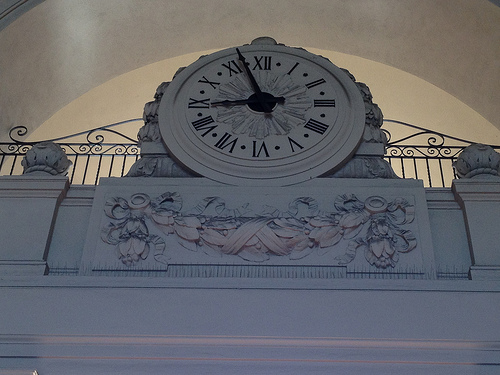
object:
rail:
[380, 116, 500, 187]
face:
[183, 50, 338, 162]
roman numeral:
[252, 54, 272, 70]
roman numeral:
[305, 78, 327, 90]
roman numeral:
[303, 117, 330, 135]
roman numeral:
[286, 135, 304, 152]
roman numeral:
[214, 132, 239, 153]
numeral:
[197, 76, 221, 90]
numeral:
[191, 116, 218, 140]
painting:
[101, 180, 422, 282]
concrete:
[22, 139, 72, 180]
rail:
[0, 118, 147, 187]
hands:
[236, 46, 272, 114]